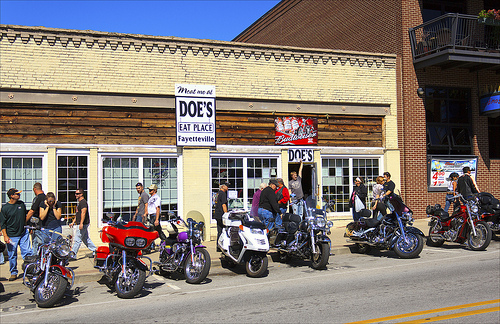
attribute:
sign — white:
[174, 83, 219, 149]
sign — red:
[274, 114, 321, 146]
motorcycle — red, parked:
[426, 193, 491, 251]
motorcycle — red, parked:
[87, 213, 161, 299]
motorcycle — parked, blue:
[344, 190, 430, 259]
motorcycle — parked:
[272, 194, 332, 271]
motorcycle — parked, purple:
[155, 212, 212, 284]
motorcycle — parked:
[25, 222, 77, 309]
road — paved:
[5, 232, 499, 322]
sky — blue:
[1, 1, 281, 43]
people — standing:
[2, 181, 64, 281]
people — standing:
[249, 158, 309, 245]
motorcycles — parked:
[94, 191, 429, 297]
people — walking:
[129, 181, 168, 241]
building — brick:
[230, 2, 499, 218]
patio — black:
[407, 13, 499, 74]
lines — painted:
[346, 299, 498, 324]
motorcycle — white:
[215, 208, 271, 277]